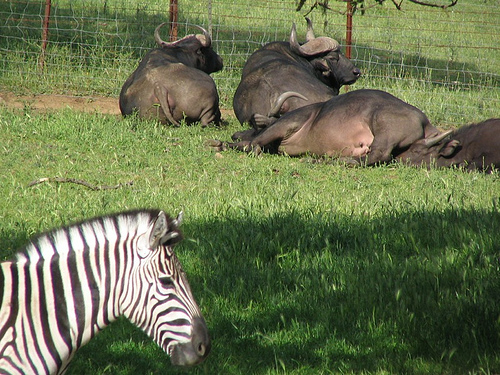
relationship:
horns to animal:
[152, 21, 212, 46] [119, 23, 223, 128]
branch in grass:
[26, 176, 133, 191] [0, 0, 500, 372]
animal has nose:
[0, 208, 211, 374] [167, 304, 214, 369]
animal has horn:
[229, 24, 353, 115] [284, 22, 303, 49]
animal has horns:
[118, 16, 225, 126] [153, 17, 213, 48]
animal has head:
[0, 208, 211, 374] [111, 210, 222, 370]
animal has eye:
[228, 32, 363, 132] [326, 50, 339, 70]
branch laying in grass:
[26, 176, 133, 191] [43, 186, 99, 213]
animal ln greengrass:
[0, 208, 211, 374] [2, 0, 499, 372]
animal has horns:
[119, 23, 223, 128] [152, 21, 212, 46]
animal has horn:
[233, 17, 361, 127] [302, 18, 317, 40]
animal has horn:
[233, 17, 361, 127] [285, 17, 305, 53]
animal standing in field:
[0, 208, 211, 374] [310, 197, 437, 308]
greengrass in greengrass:
[2, 0, 499, 372] [2, 0, 499, 372]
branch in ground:
[20, 169, 145, 202] [4, 5, 497, 365]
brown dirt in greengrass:
[17, 83, 122, 121] [2, 0, 499, 372]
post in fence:
[31, 0, 52, 72] [2, 0, 489, 113]